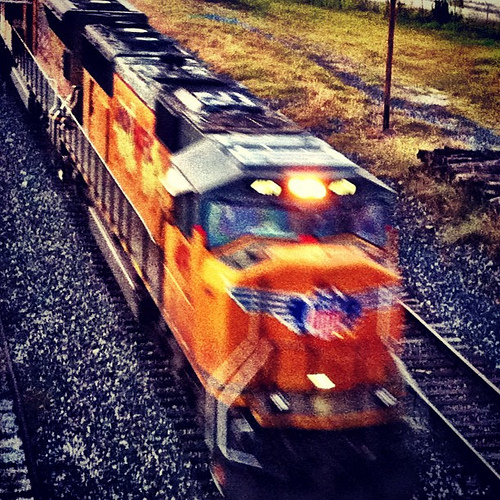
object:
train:
[0, 0, 418, 490]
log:
[382, 0, 395, 128]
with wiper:
[302, 229, 387, 254]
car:
[0, 0, 410, 499]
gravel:
[0, 59, 221, 500]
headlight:
[250, 174, 357, 201]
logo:
[225, 283, 405, 342]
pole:
[382, 0, 396, 129]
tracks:
[0, 1, 500, 500]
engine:
[255, 245, 382, 301]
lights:
[269, 391, 292, 412]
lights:
[307, 373, 336, 390]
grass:
[130, 0, 497, 246]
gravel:
[395, 192, 497, 370]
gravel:
[420, 425, 491, 497]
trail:
[218, 0, 500, 148]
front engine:
[205, 252, 406, 468]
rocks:
[0, 78, 222, 500]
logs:
[419, 146, 500, 202]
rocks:
[391, 194, 498, 431]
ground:
[0, 0, 500, 500]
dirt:
[398, 165, 445, 207]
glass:
[205, 196, 387, 250]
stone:
[50, 411, 183, 471]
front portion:
[232, 260, 412, 398]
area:
[139, 0, 480, 207]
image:
[224, 283, 407, 343]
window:
[205, 193, 391, 250]